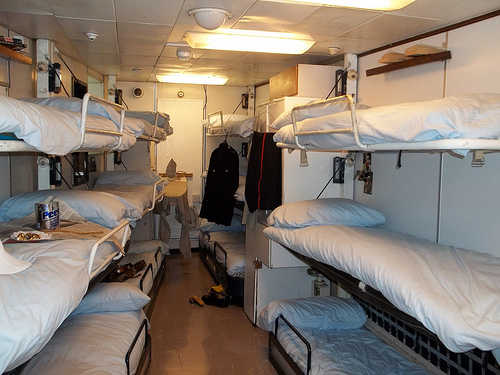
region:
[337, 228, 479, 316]
A bunk bed in a small room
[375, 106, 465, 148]
A bunk bed in a small room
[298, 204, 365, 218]
A white pillow on a bunk bed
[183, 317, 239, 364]
Brown tile floor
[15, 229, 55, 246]
Food laying on a bed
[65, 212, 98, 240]
Newspaper laying on a bed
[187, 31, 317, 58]
Ceiling lighting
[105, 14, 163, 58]
white tiled ceiling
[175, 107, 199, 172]
a closed white door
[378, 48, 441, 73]
A shelf hanging on a white wall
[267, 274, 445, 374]
bottom bunk right side of the room front beds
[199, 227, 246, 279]
bottom bunk left side of the room back beds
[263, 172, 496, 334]
middle bunk, left side of the room, front beds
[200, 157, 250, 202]
middle bunk left side of the room back beds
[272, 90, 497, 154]
top bunk left side of the room front beds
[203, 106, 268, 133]
top bunk, left side of the room, back beds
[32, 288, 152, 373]
bottom bunk, right side of the room, front beds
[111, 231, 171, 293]
bottom bunks left side of the room, back bed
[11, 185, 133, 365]
middle bunk, left side, front beds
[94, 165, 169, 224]
middle bunks left side, back beds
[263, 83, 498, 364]
A lot of beds are in the room.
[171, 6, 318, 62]
Lights are in the ceiling.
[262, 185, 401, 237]
A pillow.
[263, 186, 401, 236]
The pillow is white.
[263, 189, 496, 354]
The bed is white.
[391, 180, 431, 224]
The wall is white.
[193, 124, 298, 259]
Clothes are hanging up.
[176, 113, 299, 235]
The clothes are black.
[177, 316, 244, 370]
The floor is brown.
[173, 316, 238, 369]
The floor is glossy.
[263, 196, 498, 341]
Small bed on a board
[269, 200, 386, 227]
Pillow in a white pillowcase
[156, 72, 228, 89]
Small light pole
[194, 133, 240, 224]
Large black coat with buttons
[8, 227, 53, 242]
Plate of food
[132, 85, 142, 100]
Small black camera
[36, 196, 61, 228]
Carton of a drink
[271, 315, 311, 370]
Black arm of the bed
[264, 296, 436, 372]
Bed on the bottom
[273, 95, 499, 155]
Bed on the top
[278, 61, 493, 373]
three beds on top of each other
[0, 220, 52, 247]
there is food on the bed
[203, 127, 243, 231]
suit hanging off of a bed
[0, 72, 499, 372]
there are 12 beds in this room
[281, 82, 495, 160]
top bed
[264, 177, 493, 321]
middle bed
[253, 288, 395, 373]
bottom bed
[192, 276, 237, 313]
boots on the floor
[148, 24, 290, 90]
two lights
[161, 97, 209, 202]
there is only one door